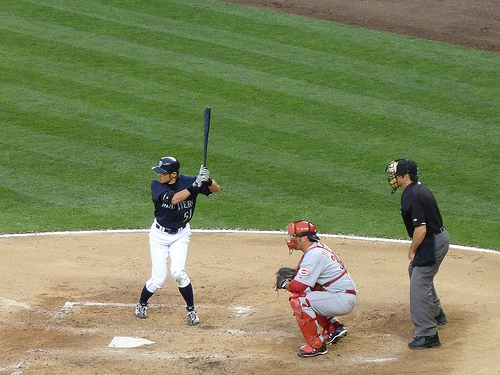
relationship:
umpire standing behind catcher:
[386, 158, 450, 349] [276, 220, 357, 356]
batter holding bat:
[135, 156, 220, 324] [202, 108, 211, 168]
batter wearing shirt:
[135, 156, 220, 324] [151, 175, 209, 227]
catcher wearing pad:
[276, 220, 357, 356] [289, 291, 322, 353]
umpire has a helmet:
[386, 158, 450, 349] [385, 158, 418, 193]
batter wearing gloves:
[135, 156, 220, 324] [195, 165, 209, 187]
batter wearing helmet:
[135, 156, 220, 324] [151, 157, 180, 175]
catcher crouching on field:
[276, 220, 357, 356] [0, 1, 499, 253]